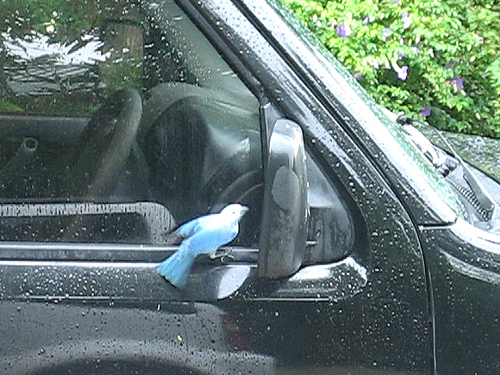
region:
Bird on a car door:
[144, 193, 237, 281]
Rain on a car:
[320, 145, 478, 353]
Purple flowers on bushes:
[368, 20, 487, 107]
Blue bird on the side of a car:
[129, 173, 255, 285]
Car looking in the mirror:
[166, 181, 265, 265]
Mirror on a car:
[237, 109, 352, 267]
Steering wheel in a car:
[52, 88, 148, 207]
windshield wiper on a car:
[400, 85, 490, 242]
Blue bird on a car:
[155, 204, 257, 310]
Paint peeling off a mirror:
[266, 153, 312, 221]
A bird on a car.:
[153, 201, 249, 293]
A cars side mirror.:
[254, 116, 309, 279]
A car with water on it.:
[3, 1, 498, 373]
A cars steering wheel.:
[52, 85, 143, 243]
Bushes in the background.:
[276, 0, 499, 140]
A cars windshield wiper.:
[396, 111, 498, 226]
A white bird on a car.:
[154, 203, 249, 293]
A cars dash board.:
[131, 80, 356, 267]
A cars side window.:
[1, 0, 263, 250]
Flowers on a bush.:
[283, 2, 499, 137]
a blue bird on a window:
[143, 190, 250, 293]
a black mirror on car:
[252, 116, 314, 275]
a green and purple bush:
[314, 4, 495, 107]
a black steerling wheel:
[33, 88, 140, 245]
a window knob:
[5, 133, 42, 190]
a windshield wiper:
[363, 92, 444, 170]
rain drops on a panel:
[297, 261, 427, 357]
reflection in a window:
[0, 1, 170, 121]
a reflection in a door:
[19, 263, 291, 364]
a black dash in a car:
[164, 93, 257, 185]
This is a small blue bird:
[129, 168, 326, 338]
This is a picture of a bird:
[63, 159, 264, 338]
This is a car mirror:
[260, 134, 340, 364]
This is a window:
[49, 186, 134, 275]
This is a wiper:
[404, 74, 496, 211]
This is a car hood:
[436, 139, 480, 171]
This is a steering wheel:
[41, 121, 180, 204]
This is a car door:
[45, 264, 112, 356]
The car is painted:
[75, 298, 159, 364]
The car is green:
[183, 311, 217, 365]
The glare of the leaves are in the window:
[7, 12, 209, 125]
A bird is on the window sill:
[137, 175, 277, 308]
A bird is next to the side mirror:
[210, 103, 462, 350]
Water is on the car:
[0, 174, 374, 364]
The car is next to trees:
[290, 3, 494, 68]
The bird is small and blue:
[147, 188, 272, 290]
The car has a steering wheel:
[41, 87, 263, 235]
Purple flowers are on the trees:
[319, 3, 472, 107]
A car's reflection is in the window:
[8, 170, 309, 314]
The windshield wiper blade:
[372, 63, 487, 187]